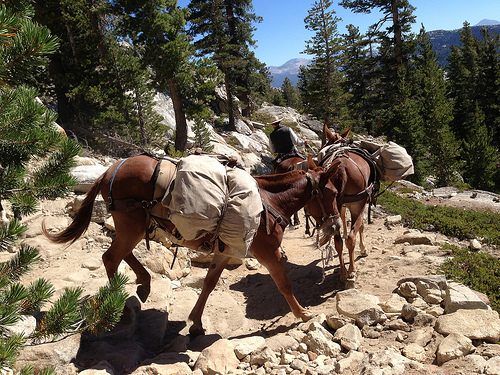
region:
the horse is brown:
[96, 122, 207, 319]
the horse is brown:
[103, 115, 284, 373]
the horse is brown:
[148, 176, 271, 346]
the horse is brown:
[155, 152, 297, 293]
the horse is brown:
[165, 53, 362, 348]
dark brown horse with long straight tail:
[41, 112, 345, 339]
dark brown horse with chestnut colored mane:
[41, 133, 348, 329]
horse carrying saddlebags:
[52, 127, 350, 348]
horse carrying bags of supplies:
[35, 127, 352, 344]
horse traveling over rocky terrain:
[29, 120, 351, 346]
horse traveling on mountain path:
[34, 132, 351, 332]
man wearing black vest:
[257, 106, 309, 166]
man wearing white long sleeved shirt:
[257, 106, 305, 167]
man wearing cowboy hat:
[257, 110, 310, 168]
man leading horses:
[254, 108, 308, 165]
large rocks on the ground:
[332, 314, 379, 359]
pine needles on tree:
[40, 284, 133, 332]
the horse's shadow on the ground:
[89, 279, 206, 367]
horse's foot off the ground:
[101, 237, 170, 313]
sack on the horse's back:
[163, 138, 293, 286]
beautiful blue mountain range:
[249, 37, 397, 102]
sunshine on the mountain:
[273, 38, 339, 80]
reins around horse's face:
[297, 191, 364, 248]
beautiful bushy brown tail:
[33, 171, 115, 256]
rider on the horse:
[243, 113, 326, 165]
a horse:
[96, 93, 363, 323]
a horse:
[156, 136, 464, 359]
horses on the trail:
[74, 65, 429, 310]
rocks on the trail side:
[288, 297, 449, 372]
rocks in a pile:
[397, 267, 493, 371]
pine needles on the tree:
[1, 250, 132, 339]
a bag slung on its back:
[165, 142, 261, 257]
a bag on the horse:
[363, 127, 421, 195]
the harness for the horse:
[263, 167, 338, 247]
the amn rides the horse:
[252, 111, 315, 170]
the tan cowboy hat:
[266, 105, 285, 125]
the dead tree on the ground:
[86, 119, 158, 159]